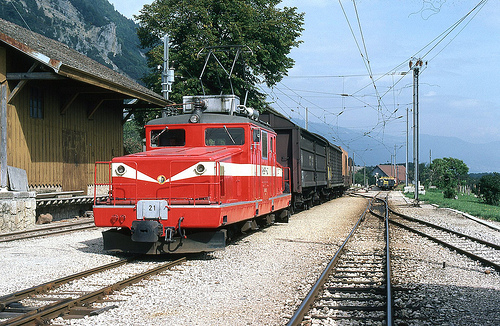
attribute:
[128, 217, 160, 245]
attachment — on front, black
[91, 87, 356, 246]
train — red, large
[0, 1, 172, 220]
waiting area — small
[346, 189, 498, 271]
tracks — steel, long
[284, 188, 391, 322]
tracks — long, steel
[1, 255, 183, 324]
tracks — long, steel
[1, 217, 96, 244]
tracks — long, steel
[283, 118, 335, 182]
train — black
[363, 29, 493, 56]
clouds — white 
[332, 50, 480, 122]
clouds — white 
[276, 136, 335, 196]
cars — train, cargo, black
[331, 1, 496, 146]
wires — overhead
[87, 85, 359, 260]
train — large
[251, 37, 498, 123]
clouds — white 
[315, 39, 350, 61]
clouds — white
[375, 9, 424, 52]
sky — Blue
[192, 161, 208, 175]
light —  the Front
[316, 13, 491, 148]
sky — blue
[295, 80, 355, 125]
clouds — white 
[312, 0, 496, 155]
sky — blue 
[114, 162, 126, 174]
train light —  train's,  the  Right,  the Front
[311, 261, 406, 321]
tracks — train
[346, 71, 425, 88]
coud — White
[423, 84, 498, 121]
coud — White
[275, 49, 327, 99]
coud — White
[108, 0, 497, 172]
sky — Blue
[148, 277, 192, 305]
rocks — little, white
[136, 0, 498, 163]
sky — blue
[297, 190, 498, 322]
train tracks — gray 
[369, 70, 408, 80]
cloud — white 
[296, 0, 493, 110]
sky — blue 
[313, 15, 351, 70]
clouds — white 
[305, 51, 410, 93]
clouds — white 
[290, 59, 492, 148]
sky — blue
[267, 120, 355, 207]
cargo unit — rear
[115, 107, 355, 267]
train engine — red 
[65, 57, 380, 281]
train — large, black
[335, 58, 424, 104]
cloud — white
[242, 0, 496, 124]
sky — blue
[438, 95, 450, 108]
sky — blue 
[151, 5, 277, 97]
leaves — green 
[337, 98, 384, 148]
clouds — white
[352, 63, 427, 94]
cloud — white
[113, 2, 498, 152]
sky — blue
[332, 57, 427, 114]
clouds — white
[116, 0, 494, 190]
sky — blue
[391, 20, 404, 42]
sky — blue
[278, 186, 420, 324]
tracks — paired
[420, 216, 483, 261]
tracks — train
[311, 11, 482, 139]
sky — blue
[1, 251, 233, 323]
tracks — train